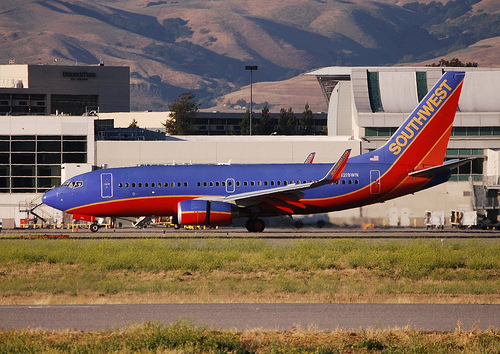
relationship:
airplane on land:
[40, 71, 479, 234] [4, 224, 496, 351]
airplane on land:
[33, 78, 474, 239] [4, 224, 496, 351]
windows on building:
[3, 133, 109, 198] [33, 52, 473, 304]